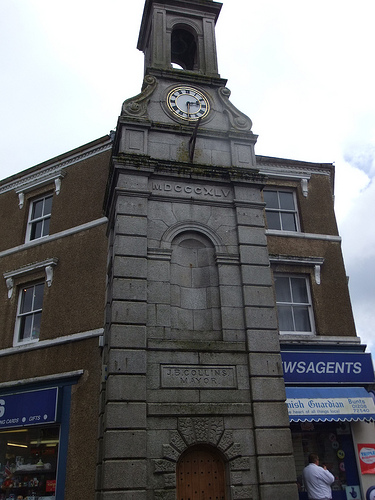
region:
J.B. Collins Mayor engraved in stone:
[156, 355, 256, 398]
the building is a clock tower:
[94, 0, 300, 496]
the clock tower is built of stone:
[96, 0, 298, 497]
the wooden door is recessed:
[153, 415, 250, 496]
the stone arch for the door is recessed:
[148, 413, 255, 496]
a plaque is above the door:
[156, 360, 235, 390]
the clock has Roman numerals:
[163, 81, 212, 122]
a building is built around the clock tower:
[3, 127, 372, 495]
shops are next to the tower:
[3, 341, 372, 496]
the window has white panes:
[4, 258, 53, 340]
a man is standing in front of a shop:
[301, 450, 335, 499]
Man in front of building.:
[302, 440, 334, 498]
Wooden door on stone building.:
[131, 423, 249, 498]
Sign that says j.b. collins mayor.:
[115, 357, 235, 401]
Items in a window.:
[8, 445, 61, 481]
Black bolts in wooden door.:
[175, 452, 225, 492]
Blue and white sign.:
[4, 379, 66, 426]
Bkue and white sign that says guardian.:
[241, 390, 359, 441]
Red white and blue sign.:
[333, 428, 369, 481]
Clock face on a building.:
[88, 73, 231, 173]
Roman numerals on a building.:
[15, 167, 252, 239]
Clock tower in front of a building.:
[120, 9, 287, 443]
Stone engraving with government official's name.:
[145, 346, 251, 412]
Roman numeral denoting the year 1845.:
[148, 171, 235, 203]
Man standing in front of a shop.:
[285, 413, 365, 499]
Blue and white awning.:
[262, 381, 373, 424]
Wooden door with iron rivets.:
[172, 439, 228, 499]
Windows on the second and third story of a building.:
[4, 180, 65, 347]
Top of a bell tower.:
[130, 1, 232, 79]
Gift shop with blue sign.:
[0, 384, 69, 496]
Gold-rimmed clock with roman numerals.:
[137, 73, 238, 132]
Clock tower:
[90, 6, 293, 495]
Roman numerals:
[141, 165, 249, 216]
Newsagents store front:
[274, 342, 369, 494]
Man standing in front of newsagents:
[291, 435, 340, 495]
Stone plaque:
[138, 345, 247, 390]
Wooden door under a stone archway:
[140, 405, 250, 495]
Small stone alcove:
[138, 201, 236, 345]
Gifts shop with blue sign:
[0, 391, 80, 482]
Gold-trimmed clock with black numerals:
[153, 69, 213, 120]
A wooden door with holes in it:
[173, 441, 220, 492]